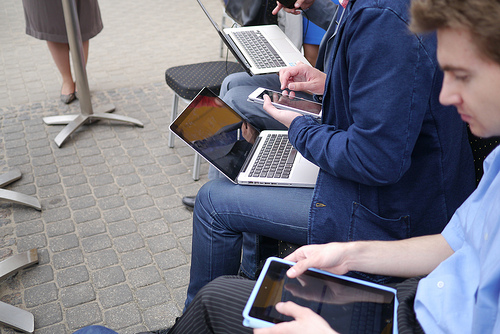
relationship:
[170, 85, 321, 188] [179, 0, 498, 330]
computer being held by a human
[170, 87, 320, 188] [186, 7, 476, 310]
computer being held by a human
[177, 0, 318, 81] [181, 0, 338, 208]
computer being held by a human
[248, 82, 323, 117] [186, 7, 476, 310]
computer being held by a human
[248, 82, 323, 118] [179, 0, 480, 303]
computer being held by a human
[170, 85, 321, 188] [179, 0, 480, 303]
computer being held by a human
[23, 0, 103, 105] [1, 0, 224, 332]
woman standing on sidewalk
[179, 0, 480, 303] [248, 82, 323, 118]
human holding computer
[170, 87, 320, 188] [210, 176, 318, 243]
computer on lap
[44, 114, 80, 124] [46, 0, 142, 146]
leg of a lectern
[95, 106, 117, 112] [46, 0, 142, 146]
leg of a lectern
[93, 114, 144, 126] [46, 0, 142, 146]
leg of a lectern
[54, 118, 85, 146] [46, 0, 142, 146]
leg of a lectern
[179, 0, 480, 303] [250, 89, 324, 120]
human using a tablet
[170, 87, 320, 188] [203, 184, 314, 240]
computer resting on lap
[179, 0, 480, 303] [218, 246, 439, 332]
human surfing internet on tablet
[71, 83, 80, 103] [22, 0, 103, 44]
shoe matches skirt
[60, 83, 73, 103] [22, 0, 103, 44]
shoe matches skirt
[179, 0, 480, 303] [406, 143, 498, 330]
human wearing shirt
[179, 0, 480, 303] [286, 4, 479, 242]
human wearing jacket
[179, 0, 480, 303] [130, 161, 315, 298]
human wearing jeans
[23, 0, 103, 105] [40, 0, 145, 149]
woman standing behind lectern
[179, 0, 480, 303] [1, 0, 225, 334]
human sitting on sidewalk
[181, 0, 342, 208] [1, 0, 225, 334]
human sitting on sidewalk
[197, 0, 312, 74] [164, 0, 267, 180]
computer beside chair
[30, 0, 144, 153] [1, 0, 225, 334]
stand on sidewalk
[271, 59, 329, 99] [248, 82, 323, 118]
hand holding computer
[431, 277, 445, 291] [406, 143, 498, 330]
button on shirt